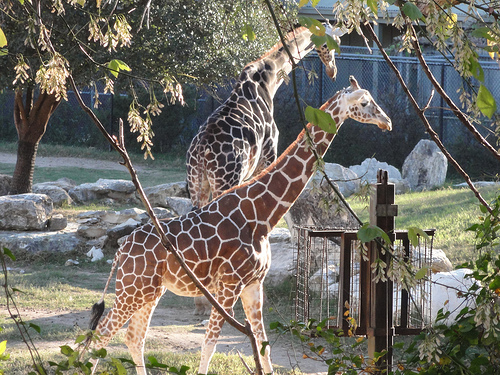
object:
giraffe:
[80, 75, 392, 375]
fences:
[0, 34, 498, 176]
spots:
[204, 205, 243, 239]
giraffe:
[183, 18, 341, 317]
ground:
[0, 140, 500, 375]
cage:
[294, 227, 434, 338]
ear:
[348, 88, 367, 102]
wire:
[288, 223, 431, 328]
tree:
[0, 0, 255, 193]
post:
[365, 169, 399, 368]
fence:
[0, 44, 500, 174]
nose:
[386, 121, 393, 131]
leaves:
[331, 0, 377, 51]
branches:
[358, 0, 499, 218]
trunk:
[4, 93, 48, 193]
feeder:
[295, 228, 433, 338]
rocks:
[0, 139, 487, 337]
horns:
[349, 74, 357, 87]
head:
[341, 74, 393, 133]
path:
[0, 227, 500, 375]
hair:
[73, 302, 106, 356]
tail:
[72, 239, 126, 355]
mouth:
[382, 124, 393, 133]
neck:
[252, 25, 317, 93]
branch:
[39, 99, 64, 132]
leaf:
[474, 85, 499, 118]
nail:
[380, 208, 386, 210]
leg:
[238, 274, 272, 370]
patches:
[242, 288, 263, 309]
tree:
[346, 0, 500, 375]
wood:
[367, 171, 397, 375]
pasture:
[0, 48, 500, 375]